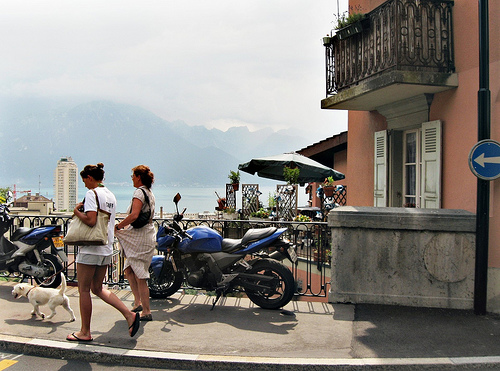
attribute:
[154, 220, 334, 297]
fence — black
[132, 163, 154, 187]
hair — brown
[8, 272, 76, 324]
dog — small, white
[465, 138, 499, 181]
sign — round, blue and white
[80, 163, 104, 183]
hair — brown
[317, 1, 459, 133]
balcony — stone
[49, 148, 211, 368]
women — walking down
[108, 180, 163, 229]
purse — small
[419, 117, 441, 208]
shutter — open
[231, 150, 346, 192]
umbrella — black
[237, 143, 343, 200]
umbrella — large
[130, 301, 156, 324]
shoes — flat